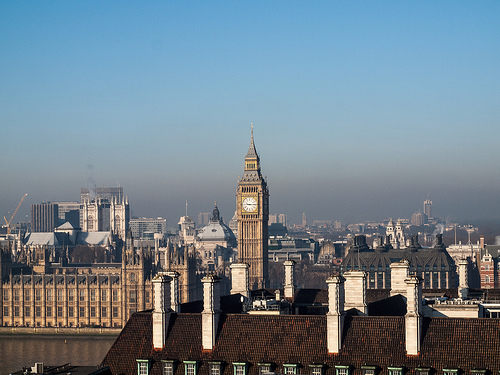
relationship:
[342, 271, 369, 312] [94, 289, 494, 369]
chimney on building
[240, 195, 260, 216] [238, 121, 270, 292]
clock on clock tower